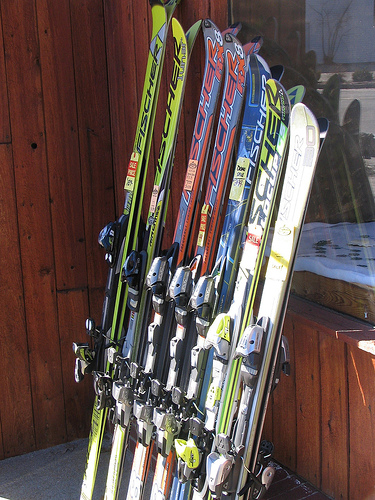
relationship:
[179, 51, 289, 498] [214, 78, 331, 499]
ski next to ski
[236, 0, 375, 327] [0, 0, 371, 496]
window of store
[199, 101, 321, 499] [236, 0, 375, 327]
merchandise in window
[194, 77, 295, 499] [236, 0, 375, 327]
merchandise in window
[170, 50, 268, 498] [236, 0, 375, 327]
merchandise in window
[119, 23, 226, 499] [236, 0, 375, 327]
merchandise in window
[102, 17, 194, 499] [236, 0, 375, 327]
merchandise in window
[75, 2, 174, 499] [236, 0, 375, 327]
merchandise in window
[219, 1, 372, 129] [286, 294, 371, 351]
store window over wood paneling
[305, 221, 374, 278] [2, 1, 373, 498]
walk area across storefront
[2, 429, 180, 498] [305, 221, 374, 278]
dusting on walk area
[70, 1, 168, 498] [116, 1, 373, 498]
ski along store front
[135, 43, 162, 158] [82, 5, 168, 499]
fischer on ski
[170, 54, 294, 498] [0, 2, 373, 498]
ski by building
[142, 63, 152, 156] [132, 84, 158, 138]
writing on ski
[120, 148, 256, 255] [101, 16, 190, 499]
tags on ski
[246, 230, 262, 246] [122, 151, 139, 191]
stripe on tag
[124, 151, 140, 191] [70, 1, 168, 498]
tag on ski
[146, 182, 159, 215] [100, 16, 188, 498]
tag on ski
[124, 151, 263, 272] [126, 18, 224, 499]
tags on ski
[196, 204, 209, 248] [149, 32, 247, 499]
tag on ski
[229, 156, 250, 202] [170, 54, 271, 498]
tag on ski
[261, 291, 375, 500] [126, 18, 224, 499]
wood paneling behind ski